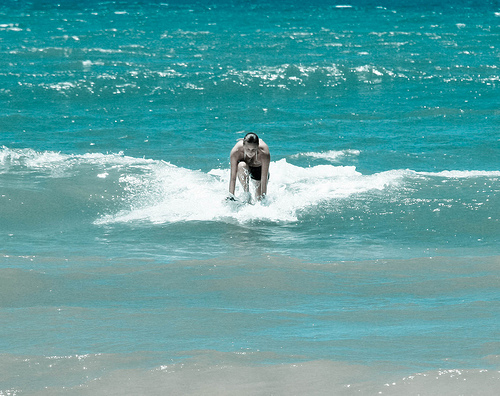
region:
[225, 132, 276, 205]
Woman on surf board catching a wave.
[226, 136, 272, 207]
Woman on surf board catching a wave.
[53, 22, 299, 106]
Waves in a blue ocean.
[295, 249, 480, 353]
waves in the water.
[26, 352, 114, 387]
Lighter colored waves in the water.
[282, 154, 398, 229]
Lots of disturbed water white in color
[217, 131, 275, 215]
this is a woman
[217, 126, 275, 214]
she is sea surfing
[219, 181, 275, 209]
her hands are surf board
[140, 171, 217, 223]
this are waves beside the girl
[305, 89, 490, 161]
the water is green in color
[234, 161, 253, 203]
the knee is bent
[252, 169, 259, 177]
she is wearing black pants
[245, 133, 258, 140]
she has black hair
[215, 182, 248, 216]
the waters are splashing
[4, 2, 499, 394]
the photo is clear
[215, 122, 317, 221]
young surfer boy in ocean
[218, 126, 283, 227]
surfer boy with hair slicked back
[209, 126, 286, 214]
boy with no shirt on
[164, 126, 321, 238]
boy with dark hair in ocean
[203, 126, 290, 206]
boy hunched over in ocean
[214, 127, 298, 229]
boy on surfboard in ocean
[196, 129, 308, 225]
boy wearing black shorts in ocean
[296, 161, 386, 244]
white waves crashing in ocean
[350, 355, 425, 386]
water meeting beach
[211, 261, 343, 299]
green clear ocean water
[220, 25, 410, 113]
part of an ocean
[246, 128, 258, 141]
part of the lady's hair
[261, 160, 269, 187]
left bicep of a lady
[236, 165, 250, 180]
right knee of a lady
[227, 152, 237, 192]
right bicep of a lady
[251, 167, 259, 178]
part of a black pant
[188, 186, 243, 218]
part of a white splash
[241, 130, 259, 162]
bent face of the lady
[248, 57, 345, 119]
some waves on the water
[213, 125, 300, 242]
a lady kneeling in water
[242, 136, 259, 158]
the head of a surfer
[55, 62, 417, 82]
a small ocean wave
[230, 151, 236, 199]
right arm of a surfer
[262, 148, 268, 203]
left arm of a surfer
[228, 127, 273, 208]
a surfer squatting low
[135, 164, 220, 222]
some white ocean foam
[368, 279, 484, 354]
a patch of ocean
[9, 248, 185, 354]
another patch of ocean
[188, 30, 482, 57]
small waves in the water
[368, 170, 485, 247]
an ocean wave forming